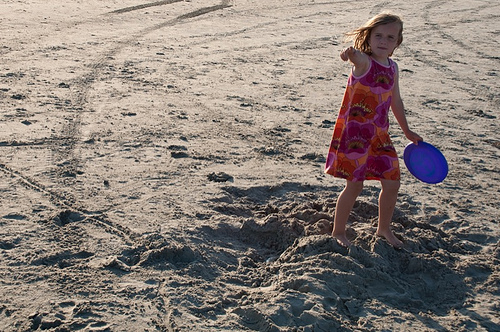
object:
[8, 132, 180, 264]
track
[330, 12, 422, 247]
girl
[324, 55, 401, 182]
dress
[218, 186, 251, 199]
shoe prints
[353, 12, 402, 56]
head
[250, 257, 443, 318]
sand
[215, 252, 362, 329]
mounded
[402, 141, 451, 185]
disk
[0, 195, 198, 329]
in sand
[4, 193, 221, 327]
ground